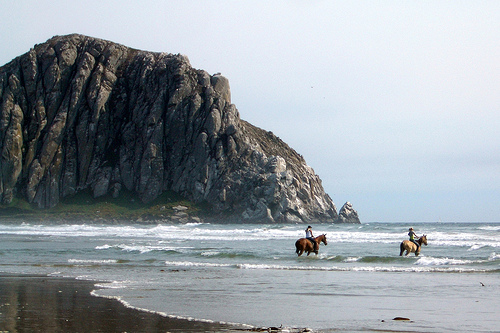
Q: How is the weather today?
A: It is cloudy.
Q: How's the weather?
A: It is cloudy.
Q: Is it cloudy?
A: Yes, it is cloudy.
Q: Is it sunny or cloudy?
A: It is cloudy.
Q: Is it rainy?
A: No, it is cloudy.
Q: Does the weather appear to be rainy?
A: No, it is cloudy.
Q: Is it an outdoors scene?
A: Yes, it is outdoors.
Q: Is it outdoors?
A: Yes, it is outdoors.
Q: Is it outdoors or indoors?
A: It is outdoors.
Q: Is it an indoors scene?
A: No, it is outdoors.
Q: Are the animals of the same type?
A: Yes, all the animals are horses.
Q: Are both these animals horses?
A: Yes, all the animals are horses.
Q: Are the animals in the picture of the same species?
A: Yes, all the animals are horses.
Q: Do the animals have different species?
A: No, all the animals are horses.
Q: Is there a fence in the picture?
A: No, there are no fences.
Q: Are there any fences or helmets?
A: No, there are no fences or helmets.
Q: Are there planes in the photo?
A: No, there are no planes.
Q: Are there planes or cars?
A: No, there are no planes or cars.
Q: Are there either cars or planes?
A: No, there are no planes or cars.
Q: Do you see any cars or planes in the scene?
A: No, there are no planes or cars.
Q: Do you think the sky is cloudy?
A: Yes, the sky is cloudy.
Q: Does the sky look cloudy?
A: Yes, the sky is cloudy.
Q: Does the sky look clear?
A: No, the sky is cloudy.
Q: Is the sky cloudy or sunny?
A: The sky is cloudy.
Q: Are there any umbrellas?
A: No, there are no umbrellas.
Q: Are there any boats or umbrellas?
A: No, there are no umbrellas or boats.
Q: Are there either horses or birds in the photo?
A: Yes, there is a horse.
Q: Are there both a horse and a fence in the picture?
A: No, there is a horse but no fences.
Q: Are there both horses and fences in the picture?
A: No, there is a horse but no fences.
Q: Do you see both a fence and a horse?
A: No, there is a horse but no fences.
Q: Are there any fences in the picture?
A: No, there are no fences.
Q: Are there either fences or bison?
A: No, there are no fences or bison.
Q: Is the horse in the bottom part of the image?
A: Yes, the horse is in the bottom of the image.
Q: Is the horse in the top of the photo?
A: No, the horse is in the bottom of the image.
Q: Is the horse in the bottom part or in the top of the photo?
A: The horse is in the bottom of the image.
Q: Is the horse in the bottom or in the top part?
A: The horse is in the bottom of the image.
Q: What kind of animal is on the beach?
A: The animal is a horse.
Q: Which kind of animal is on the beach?
A: The animal is a horse.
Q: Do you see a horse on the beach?
A: Yes, there is a horse on the beach.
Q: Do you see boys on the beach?
A: No, there is a horse on the beach.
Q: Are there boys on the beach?
A: No, there is a horse on the beach.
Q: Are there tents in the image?
A: No, there are no tents.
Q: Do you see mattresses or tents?
A: No, there are no tents or mattresses.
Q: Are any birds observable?
A: No, there are no birds.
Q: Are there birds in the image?
A: No, there are no birds.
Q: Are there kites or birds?
A: No, there are no birds or kites.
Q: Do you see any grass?
A: Yes, there is grass.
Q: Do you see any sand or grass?
A: Yes, there is grass.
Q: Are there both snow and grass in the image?
A: No, there is grass but no snow.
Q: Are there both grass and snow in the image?
A: No, there is grass but no snow.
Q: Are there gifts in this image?
A: No, there are no gifts.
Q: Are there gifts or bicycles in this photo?
A: No, there are no gifts or bicycles.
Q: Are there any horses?
A: Yes, there is a horse.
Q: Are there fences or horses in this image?
A: Yes, there is a horse.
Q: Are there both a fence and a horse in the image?
A: No, there is a horse but no fences.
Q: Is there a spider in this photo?
A: No, there are no spiders.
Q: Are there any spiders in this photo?
A: No, there are no spiders.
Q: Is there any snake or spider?
A: No, there are no spiders or snakes.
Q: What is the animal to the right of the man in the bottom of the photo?
A: The animal is a horse.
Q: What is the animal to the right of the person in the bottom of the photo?
A: The animal is a horse.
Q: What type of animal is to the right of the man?
A: The animal is a horse.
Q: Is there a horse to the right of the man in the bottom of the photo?
A: Yes, there is a horse to the right of the man.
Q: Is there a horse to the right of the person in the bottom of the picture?
A: Yes, there is a horse to the right of the man.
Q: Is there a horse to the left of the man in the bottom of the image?
A: No, the horse is to the right of the man.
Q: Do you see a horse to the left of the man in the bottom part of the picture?
A: No, the horse is to the right of the man.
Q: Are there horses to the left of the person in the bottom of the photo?
A: No, the horse is to the right of the man.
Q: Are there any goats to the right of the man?
A: No, there is a horse to the right of the man.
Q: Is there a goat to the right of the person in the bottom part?
A: No, there is a horse to the right of the man.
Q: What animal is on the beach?
A: The animal is a horse.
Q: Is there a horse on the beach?
A: Yes, there is a horse on the beach.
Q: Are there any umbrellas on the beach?
A: No, there is a horse on the beach.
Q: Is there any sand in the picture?
A: Yes, there is sand.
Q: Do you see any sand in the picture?
A: Yes, there is sand.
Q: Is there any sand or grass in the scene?
A: Yes, there is sand.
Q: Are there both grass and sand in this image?
A: Yes, there are both sand and grass.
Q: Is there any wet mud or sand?
A: Yes, there is wet sand.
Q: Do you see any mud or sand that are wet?
A: Yes, the sand is wet.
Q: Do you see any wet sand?
A: Yes, there is wet sand.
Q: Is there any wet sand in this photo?
A: Yes, there is wet sand.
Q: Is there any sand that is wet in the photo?
A: Yes, there is wet sand.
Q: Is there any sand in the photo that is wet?
A: Yes, there is sand that is wet.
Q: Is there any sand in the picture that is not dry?
A: Yes, there is wet sand.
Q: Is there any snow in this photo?
A: No, there is no snow.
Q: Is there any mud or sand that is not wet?
A: No, there is sand but it is wet.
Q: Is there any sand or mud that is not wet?
A: No, there is sand but it is wet.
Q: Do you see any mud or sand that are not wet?
A: No, there is sand but it is wet.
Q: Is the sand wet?
A: Yes, the sand is wet.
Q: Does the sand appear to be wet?
A: Yes, the sand is wet.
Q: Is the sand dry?
A: No, the sand is wet.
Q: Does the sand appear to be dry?
A: No, the sand is wet.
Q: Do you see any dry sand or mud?
A: No, there is sand but it is wet.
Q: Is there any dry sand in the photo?
A: No, there is sand but it is wet.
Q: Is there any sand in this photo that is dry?
A: No, there is sand but it is wet.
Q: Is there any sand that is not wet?
A: No, there is sand but it is wet.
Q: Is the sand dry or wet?
A: The sand is wet.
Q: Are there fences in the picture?
A: No, there are no fences.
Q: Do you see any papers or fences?
A: No, there are no fences or papers.